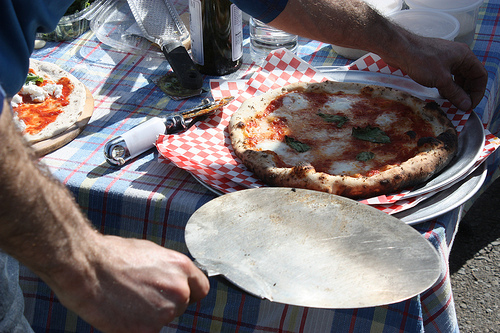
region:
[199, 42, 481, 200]
a pizza on a round pan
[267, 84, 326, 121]
melted cheese on a pizza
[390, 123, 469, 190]
crust on a pizza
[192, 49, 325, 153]
red and white checkard paper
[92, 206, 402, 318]
a person holding a round pizza tray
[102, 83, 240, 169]
a pizza cutter with a white handle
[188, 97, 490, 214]
a pizza on a table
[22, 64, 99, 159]
a pizza on a wood cutting board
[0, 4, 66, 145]
a man wearing a blue shirt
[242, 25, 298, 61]
a clear water glass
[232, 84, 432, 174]
this is a pizza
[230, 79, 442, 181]
the pizza is round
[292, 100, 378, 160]
the pizza is red in color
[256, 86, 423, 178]
the pizza is big in size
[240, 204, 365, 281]
this is a pan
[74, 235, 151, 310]
this is the hand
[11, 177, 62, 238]
the hand is hairy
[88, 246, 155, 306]
the hand is light skinned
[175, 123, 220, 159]
this is a saviet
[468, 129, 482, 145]
this is a tray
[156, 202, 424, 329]
FLAT PIZZA PAN UNDER PIZZA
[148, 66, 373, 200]
RED AND WHITE CHECKERED PAPER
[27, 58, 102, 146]
PIZZA ON LEFT OF TABLE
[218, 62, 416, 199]
PIZZA ON RIGHT OF TABLE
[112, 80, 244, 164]
PIZZA CUTTER ON LEFT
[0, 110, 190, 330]
MAN'S ARM ON LEFT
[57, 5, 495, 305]
BLUE TABLE CLOTH ON TABLE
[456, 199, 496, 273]
CONCRETE WALL BEHIND TABLE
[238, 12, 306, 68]
WATER BOTTLE ON TABLE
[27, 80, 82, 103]
WHITE CLUMPS OF CHEESE ON PIZZA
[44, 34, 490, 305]
a pizza on a tray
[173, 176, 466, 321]
a pan for carrying the pizza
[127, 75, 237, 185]
a pizza cutter for cutting slices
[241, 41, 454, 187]
this pie has cheese and sauce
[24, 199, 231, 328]
his hand is holding the handle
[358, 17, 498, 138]
his hand his grabbing the pizza pan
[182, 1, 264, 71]
a bottle on the table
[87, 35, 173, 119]
a blue plaid tablecloth underneath the pizza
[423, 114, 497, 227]
two pizza pans are stacked up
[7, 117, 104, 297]
this man has a hairy arm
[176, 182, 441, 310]
Empty metal pan.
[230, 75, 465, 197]
Pizza ready to be served.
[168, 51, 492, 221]
Stack of pizza trays with red and white checked paper on them.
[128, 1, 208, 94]
Cheese grater.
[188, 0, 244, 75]
Dark bottle with white lable.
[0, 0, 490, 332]
A man preparing to serve pizza.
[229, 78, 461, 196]
Unsliced pizza.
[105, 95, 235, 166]
Pizza cutter.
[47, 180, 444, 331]
Man's hand holding a round metal tray.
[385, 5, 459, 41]
Plastic cup.